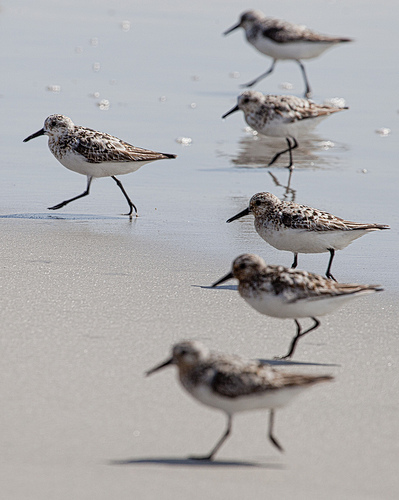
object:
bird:
[143, 334, 336, 463]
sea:
[0, 0, 399, 282]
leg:
[210, 413, 234, 456]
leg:
[265, 405, 285, 451]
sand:
[0, 208, 398, 500]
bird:
[211, 252, 387, 362]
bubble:
[175, 136, 190, 145]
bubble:
[154, 95, 171, 104]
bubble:
[90, 61, 101, 74]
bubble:
[374, 125, 392, 139]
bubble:
[359, 166, 369, 176]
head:
[221, 89, 267, 124]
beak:
[225, 206, 249, 222]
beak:
[23, 129, 44, 141]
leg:
[57, 176, 90, 208]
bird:
[221, 86, 349, 171]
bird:
[22, 114, 176, 222]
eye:
[49, 123, 59, 131]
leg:
[111, 175, 132, 204]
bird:
[227, 190, 393, 285]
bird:
[221, 6, 358, 98]